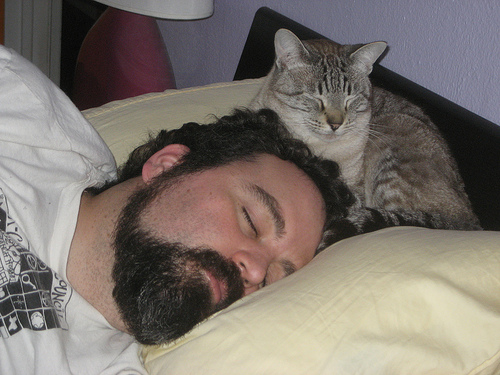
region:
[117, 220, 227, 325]
brown beard on sleeping man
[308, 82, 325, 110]
closed eye of sleeping cat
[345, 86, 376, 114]
closed eye of sleeping cat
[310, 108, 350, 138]
nose of sleeping cat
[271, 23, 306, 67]
gray ear of sleeping cat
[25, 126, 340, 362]
a man sleeping in a bed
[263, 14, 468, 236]
a cat sleeping next to a man's head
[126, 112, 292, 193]
a man with black hair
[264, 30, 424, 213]
a grey striped cat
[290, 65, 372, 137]
a cat with its eyes closed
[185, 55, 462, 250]
a man sleeping next to a cat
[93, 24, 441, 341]
a man and a cat on a bed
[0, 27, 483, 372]
man and cat sleeping in bed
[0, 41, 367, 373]
man sleeping on a pillow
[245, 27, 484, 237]
gray and black cat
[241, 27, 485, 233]
cat sleeping on a pillow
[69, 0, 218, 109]
red lamp with white shade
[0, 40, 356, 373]
man wearing a white shirt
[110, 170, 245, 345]
thick black and gray facial hair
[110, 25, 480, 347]
cat sleeping next to a man's head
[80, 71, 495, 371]
large white bed pillow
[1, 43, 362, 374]
man with his eyes closed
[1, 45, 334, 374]
man is sleeping on his pillow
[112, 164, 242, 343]
man has brown and gray beard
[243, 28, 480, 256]
cat is asleep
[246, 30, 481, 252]
cat is a gray tabby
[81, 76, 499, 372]
pillow is off white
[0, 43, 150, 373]
shirt is white and black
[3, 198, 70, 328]
shirt has black writing on it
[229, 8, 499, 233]
headboard is dark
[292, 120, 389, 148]
cats whiskers are white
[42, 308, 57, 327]
black square on shirt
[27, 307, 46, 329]
black square on shirt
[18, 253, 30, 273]
black square on shirt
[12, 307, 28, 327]
black square on shirt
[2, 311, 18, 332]
black square on shirt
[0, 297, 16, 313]
black square on shirt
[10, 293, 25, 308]
black square on shirt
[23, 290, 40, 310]
black square on shirt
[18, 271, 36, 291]
black square on shirt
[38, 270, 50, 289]
black square on shirt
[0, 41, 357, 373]
man has his eyes closed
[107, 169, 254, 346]
man has a shaggy beard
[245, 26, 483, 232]
gray cat above man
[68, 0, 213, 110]
lamp behind the bed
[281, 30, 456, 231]
A cat sleeping on a bed.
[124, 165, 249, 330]
A beard on a face.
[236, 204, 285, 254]
A eye on a face.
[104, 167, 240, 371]
A beard on a face.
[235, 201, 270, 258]
An eye on a face.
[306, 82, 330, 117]
An eye on a face.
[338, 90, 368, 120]
An eye on a face.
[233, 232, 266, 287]
A nose on a face.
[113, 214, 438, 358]
A pillow on a bed.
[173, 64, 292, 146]
A pillow on a bed.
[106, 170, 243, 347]
thick black and grey facial hair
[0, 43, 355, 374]
man wearing white shirt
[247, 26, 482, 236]
grey and white cat sleeping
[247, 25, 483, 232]
cat curled up behind head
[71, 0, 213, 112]
lamp with red base and white shade